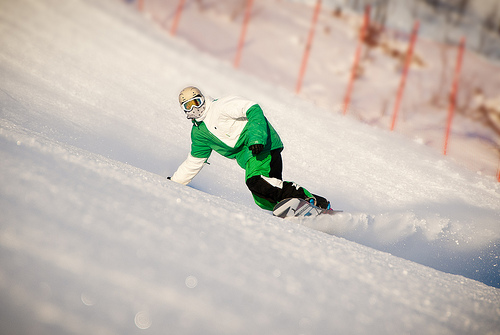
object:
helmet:
[179, 86, 205, 119]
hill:
[0, 120, 500, 335]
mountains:
[0, 0, 500, 335]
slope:
[0, 0, 495, 334]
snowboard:
[272, 197, 344, 219]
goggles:
[182, 96, 204, 111]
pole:
[230, 0, 253, 69]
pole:
[292, 0, 321, 95]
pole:
[341, 0, 369, 112]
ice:
[110, 61, 465, 243]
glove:
[248, 144, 264, 156]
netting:
[133, 0, 499, 178]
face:
[181, 97, 208, 120]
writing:
[273, 198, 322, 226]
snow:
[126, 202, 303, 305]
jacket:
[170, 95, 284, 187]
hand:
[249, 142, 264, 155]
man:
[166, 85, 330, 218]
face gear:
[178, 85, 205, 119]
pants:
[243, 149, 333, 217]